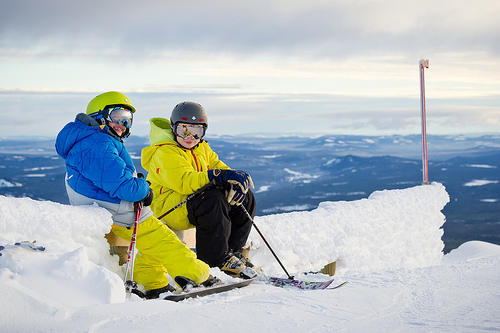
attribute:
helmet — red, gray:
[152, 94, 234, 155]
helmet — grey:
[169, 100, 209, 130]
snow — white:
[63, 287, 160, 324]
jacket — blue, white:
[158, 144, 191, 171]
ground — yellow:
[406, 147, 422, 162]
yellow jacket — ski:
[138, 113, 232, 231]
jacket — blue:
[125, 126, 239, 226]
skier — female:
[143, 98, 344, 290]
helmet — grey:
[171, 100, 213, 138]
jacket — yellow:
[142, 110, 234, 239]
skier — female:
[140, 97, 267, 286]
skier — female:
[48, 85, 224, 305]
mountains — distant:
[7, 89, 499, 149]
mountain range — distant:
[5, 88, 498, 232]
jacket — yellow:
[136, 113, 228, 233]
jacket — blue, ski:
[51, 117, 152, 204]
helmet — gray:
[148, 84, 233, 162]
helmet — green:
[69, 97, 137, 109]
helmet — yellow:
[87, 90, 138, 113]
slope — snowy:
[1, 180, 496, 330]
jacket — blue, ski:
[54, 118, 158, 217]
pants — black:
[175, 179, 259, 273]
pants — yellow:
[107, 217, 212, 296]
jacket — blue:
[54, 111, 152, 226]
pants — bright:
[105, 212, 212, 291]